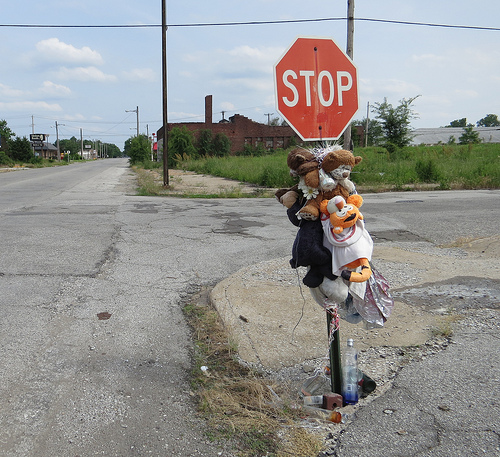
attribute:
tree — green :
[380, 86, 417, 162]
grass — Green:
[186, 141, 499, 191]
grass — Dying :
[182, 303, 287, 438]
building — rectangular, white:
[379, 124, 497, 146]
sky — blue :
[386, 48, 453, 87]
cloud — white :
[18, 37, 96, 67]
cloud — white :
[37, 61, 114, 83]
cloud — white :
[200, 39, 264, 81]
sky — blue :
[11, 4, 271, 97]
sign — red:
[258, 25, 370, 150]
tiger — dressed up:
[316, 192, 376, 288]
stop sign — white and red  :
[264, 39, 355, 145]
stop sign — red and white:
[269, 32, 362, 401]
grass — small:
[197, 118, 274, 195]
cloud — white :
[16, 38, 107, 74]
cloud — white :
[5, 37, 101, 72]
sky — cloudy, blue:
[2, 2, 482, 155]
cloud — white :
[10, 37, 107, 67]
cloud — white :
[14, 34, 104, 71]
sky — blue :
[1, 1, 484, 138]